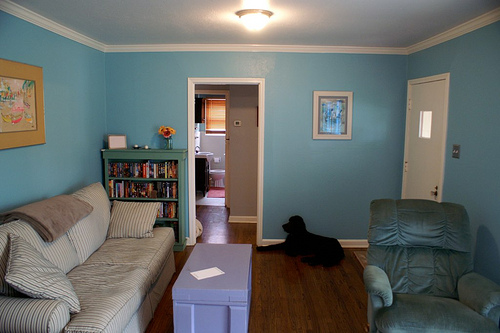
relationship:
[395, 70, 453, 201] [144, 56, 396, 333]
door to outside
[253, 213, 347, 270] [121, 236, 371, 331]
dog laying on floor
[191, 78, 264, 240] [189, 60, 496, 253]
doorway to or parts of house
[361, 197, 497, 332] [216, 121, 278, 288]
chair facing away from door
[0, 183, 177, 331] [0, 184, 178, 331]
couch with stripes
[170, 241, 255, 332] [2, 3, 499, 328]
table for coffee in middle of room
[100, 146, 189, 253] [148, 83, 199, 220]
bookcase in back of room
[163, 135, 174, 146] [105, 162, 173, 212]
vase with flowers on bookcase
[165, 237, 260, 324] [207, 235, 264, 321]
table in photo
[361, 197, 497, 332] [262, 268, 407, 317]
chair in photo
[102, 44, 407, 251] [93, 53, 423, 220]
wall hanging in photo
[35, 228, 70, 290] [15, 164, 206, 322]
pillow on couch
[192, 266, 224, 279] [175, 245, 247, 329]
paper sheet on table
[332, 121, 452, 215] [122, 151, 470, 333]
closed door in photo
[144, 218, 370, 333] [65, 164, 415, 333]
floor in photo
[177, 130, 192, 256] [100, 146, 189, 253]
part of a short bookcase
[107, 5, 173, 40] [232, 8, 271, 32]
ceiling has light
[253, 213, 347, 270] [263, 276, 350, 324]
dog laying on floor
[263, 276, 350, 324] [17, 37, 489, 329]
floor in living room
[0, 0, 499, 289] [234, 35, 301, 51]
wall have white molding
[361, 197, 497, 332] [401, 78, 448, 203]
chair by door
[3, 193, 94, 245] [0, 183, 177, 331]
blanket on back of couch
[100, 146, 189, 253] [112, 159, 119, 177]
bookcase filled with book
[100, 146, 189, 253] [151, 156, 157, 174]
bookcase filled with book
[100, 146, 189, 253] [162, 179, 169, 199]
bookcase filled with book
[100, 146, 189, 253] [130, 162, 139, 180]
bookcase filled with book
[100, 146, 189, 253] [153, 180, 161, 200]
bookcase filled with book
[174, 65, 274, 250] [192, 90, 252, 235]
door frame leading to room